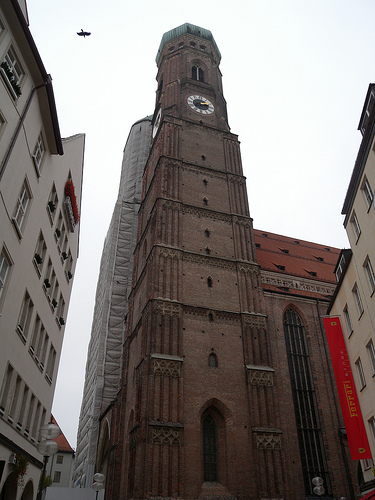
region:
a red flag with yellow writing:
[319, 313, 373, 478]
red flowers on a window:
[62, 165, 81, 233]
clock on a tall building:
[182, 93, 227, 120]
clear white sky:
[238, 97, 352, 230]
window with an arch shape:
[193, 384, 233, 495]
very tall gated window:
[278, 299, 337, 498]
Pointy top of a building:
[68, 119, 94, 177]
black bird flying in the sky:
[67, 23, 97, 46]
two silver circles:
[304, 470, 329, 499]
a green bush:
[10, 442, 36, 487]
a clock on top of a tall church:
[182, 87, 222, 121]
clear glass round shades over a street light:
[307, 475, 328, 499]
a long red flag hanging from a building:
[317, 310, 373, 462]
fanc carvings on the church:
[253, 430, 283, 451]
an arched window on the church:
[193, 395, 239, 497]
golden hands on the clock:
[198, 100, 209, 104]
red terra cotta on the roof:
[59, 438, 69, 447]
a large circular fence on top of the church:
[180, 23, 211, 35]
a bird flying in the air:
[70, 21, 96, 46]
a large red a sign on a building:
[65, 180, 84, 230]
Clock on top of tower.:
[186, 92, 221, 119]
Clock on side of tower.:
[145, 102, 165, 142]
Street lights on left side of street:
[31, 408, 64, 496]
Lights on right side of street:
[305, 473, 329, 498]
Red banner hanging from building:
[316, 307, 372, 469]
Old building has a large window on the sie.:
[277, 299, 343, 494]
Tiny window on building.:
[204, 349, 220, 371]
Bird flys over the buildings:
[72, 20, 95, 40]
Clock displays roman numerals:
[182, 89, 216, 119]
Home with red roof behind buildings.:
[50, 410, 79, 491]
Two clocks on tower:
[145, 87, 217, 142]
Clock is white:
[183, 90, 218, 116]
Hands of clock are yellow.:
[197, 98, 213, 108]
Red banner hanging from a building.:
[315, 307, 373, 469]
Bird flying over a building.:
[69, 23, 92, 42]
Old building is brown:
[97, 11, 358, 498]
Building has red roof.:
[251, 229, 338, 292]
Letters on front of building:
[48, 161, 94, 241]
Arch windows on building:
[186, 394, 240, 496]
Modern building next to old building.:
[316, 70, 373, 498]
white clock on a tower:
[184, 92, 220, 116]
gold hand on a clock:
[195, 97, 213, 109]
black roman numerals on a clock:
[186, 90, 219, 118]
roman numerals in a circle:
[184, 93, 217, 116]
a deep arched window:
[190, 393, 239, 492]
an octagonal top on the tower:
[132, 20, 240, 142]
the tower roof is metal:
[150, 18, 226, 74]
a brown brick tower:
[97, 32, 301, 497]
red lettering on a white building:
[52, 178, 81, 244]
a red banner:
[313, 307, 373, 466]